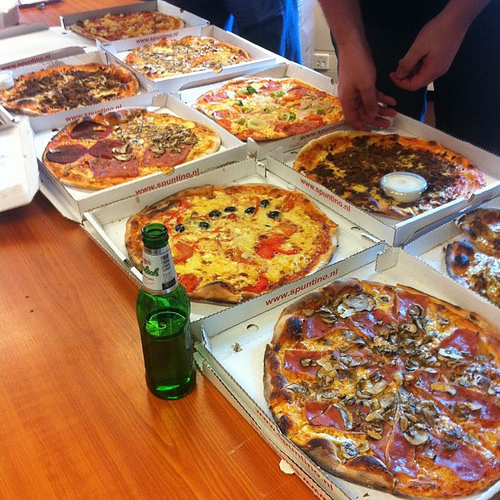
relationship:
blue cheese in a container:
[378, 163, 425, 208] [385, 166, 426, 203]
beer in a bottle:
[137, 228, 197, 405] [137, 227, 203, 411]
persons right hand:
[327, 2, 499, 146] [325, 51, 393, 137]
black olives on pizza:
[168, 197, 285, 231] [113, 172, 312, 293]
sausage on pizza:
[11, 72, 122, 104] [10, 64, 141, 119]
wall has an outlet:
[307, 9, 363, 76] [308, 47, 337, 72]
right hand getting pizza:
[325, 51, 393, 137] [306, 128, 463, 214]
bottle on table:
[137, 227, 203, 411] [12, 10, 372, 496]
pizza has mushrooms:
[61, 115, 216, 180] [120, 113, 196, 156]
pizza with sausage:
[306, 128, 463, 214] [11, 72, 122, 104]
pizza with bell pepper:
[218, 77, 335, 120] [230, 74, 326, 129]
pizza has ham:
[61, 115, 216, 180] [81, 122, 215, 181]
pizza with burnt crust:
[287, 295, 495, 467] [264, 271, 397, 483]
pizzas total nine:
[19, 1, 493, 480] [41, 17, 498, 464]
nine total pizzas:
[41, 17, 498, 464] [19, 1, 493, 480]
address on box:
[259, 269, 362, 314] [124, 165, 364, 303]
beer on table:
[137, 228, 197, 405] [35, 223, 261, 496]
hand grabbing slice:
[325, 51, 393, 137] [340, 124, 404, 179]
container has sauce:
[385, 166, 426, 203] [366, 159, 438, 210]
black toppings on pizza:
[156, 194, 315, 241] [113, 172, 312, 293]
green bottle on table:
[137, 228, 197, 405] [12, 10, 372, 496]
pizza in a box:
[62, 2, 200, 33] [63, 12, 211, 39]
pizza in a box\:
[130, 41, 264, 72] [114, 23, 254, 85]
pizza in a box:
[194, 77, 348, 142] [124, 165, 364, 303]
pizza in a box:
[306, 128, 463, 214] [320, 83, 461, 247]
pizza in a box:
[449, 179, 498, 313] [450, 191, 499, 299]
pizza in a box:
[5, 28, 123, 110] [11, 42, 137, 121]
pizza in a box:
[61, 115, 216, 180] [37, 78, 238, 204]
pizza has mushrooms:
[287, 295, 495, 467] [288, 267, 456, 477]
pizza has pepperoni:
[261, 276, 500, 500] [285, 293, 481, 474]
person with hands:
[327, 2, 499, 146] [336, 37, 453, 109]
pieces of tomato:
[165, 179, 281, 270] [178, 244, 325, 295]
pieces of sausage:
[306, 128, 463, 214] [307, 127, 456, 206]